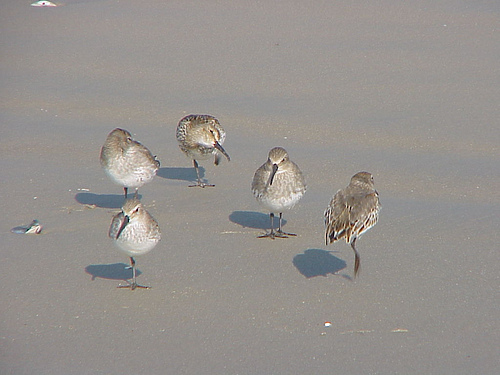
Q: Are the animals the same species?
A: Yes, all the animals are birds.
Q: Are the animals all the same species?
A: Yes, all the animals are birds.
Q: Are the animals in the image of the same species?
A: Yes, all the animals are birds.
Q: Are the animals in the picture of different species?
A: No, all the animals are birds.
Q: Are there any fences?
A: No, there are no fences.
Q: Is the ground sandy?
A: Yes, the ground is sandy.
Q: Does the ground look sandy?
A: Yes, the ground is sandy.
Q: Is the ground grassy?
A: No, the ground is sandy.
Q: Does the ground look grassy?
A: No, the ground is sandy.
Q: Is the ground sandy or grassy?
A: The ground is sandy.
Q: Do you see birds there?
A: Yes, there are birds.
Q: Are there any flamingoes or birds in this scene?
A: Yes, there are birds.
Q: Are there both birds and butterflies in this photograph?
A: No, there are birds but no butterflies.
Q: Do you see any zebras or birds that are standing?
A: Yes, the birds are standing.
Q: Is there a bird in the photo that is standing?
A: Yes, there are birds that are standing.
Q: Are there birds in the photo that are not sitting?
A: Yes, there are birds that are standing.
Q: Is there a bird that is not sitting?
A: Yes, there are birds that are standing.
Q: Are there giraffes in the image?
A: No, there are no giraffes.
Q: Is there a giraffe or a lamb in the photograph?
A: No, there are no giraffes or lambs.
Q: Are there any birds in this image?
A: Yes, there is a bird.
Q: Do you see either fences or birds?
A: Yes, there is a bird.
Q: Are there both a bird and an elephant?
A: No, there is a bird but no elephants.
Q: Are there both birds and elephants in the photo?
A: No, there is a bird but no elephants.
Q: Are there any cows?
A: No, there are no cows.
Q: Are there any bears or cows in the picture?
A: No, there are no cows or bears.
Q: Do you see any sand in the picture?
A: Yes, there is sand.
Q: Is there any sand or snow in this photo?
A: Yes, there is sand.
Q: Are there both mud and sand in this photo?
A: No, there is sand but no mud.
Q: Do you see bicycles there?
A: No, there are no bicycles.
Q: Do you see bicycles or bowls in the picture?
A: No, there are no bicycles or bowls.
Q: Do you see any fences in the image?
A: No, there are no fences.